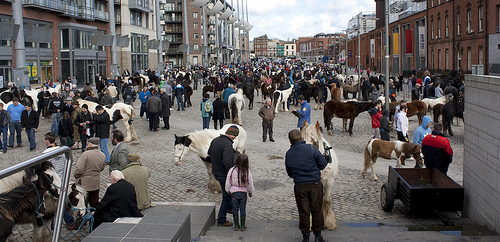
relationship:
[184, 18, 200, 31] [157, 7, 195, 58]
window on building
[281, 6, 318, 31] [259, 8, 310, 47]
cloud in sky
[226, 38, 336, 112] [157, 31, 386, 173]
people in crowd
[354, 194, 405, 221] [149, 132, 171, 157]
brick in ground